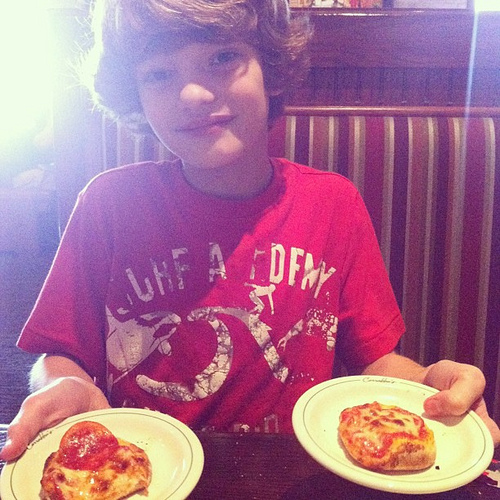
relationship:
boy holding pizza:
[108, 30, 335, 244] [345, 397, 440, 468]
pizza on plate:
[345, 397, 440, 468] [304, 390, 333, 438]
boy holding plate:
[108, 30, 335, 244] [304, 390, 333, 438]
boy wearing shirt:
[108, 30, 335, 244] [171, 202, 306, 319]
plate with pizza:
[304, 390, 333, 438] [345, 397, 440, 468]